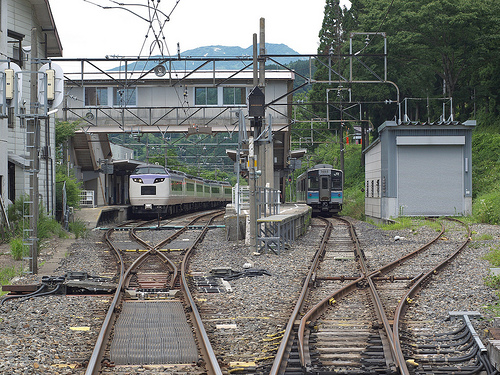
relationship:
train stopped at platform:
[129, 161, 235, 218] [75, 204, 138, 226]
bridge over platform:
[61, 105, 250, 135] [75, 204, 138, 226]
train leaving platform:
[129, 161, 235, 218] [75, 204, 138, 226]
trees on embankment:
[305, 0, 499, 121] [299, 108, 499, 220]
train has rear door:
[293, 166, 345, 217] [320, 176, 331, 199]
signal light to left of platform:
[155, 65, 165, 77] [257, 200, 319, 253]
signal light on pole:
[36, 61, 67, 111] [29, 26, 43, 275]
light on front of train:
[154, 176, 165, 184] [129, 161, 235, 218]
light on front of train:
[131, 176, 142, 184] [129, 161, 235, 218]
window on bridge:
[84, 87, 109, 106] [61, 69, 294, 135]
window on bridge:
[113, 87, 136, 106] [61, 69, 294, 135]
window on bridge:
[196, 84, 219, 104] [61, 69, 294, 135]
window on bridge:
[223, 85, 246, 105] [61, 69, 294, 135]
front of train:
[128, 165, 170, 216] [129, 161, 235, 218]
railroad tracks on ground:
[88, 209, 225, 374] [0, 205, 500, 374]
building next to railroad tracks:
[0, 3, 64, 226] [88, 209, 225, 374]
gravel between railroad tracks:
[185, 214, 324, 373] [88, 209, 225, 374]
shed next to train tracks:
[361, 118, 476, 219] [270, 218, 472, 374]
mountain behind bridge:
[113, 41, 312, 70] [61, 69, 294, 135]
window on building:
[13, 48, 25, 65] [0, 3, 64, 226]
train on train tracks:
[293, 166, 345, 217] [270, 218, 472, 374]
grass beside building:
[39, 216, 71, 241] [0, 3, 64, 226]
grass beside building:
[11, 237, 25, 260] [0, 3, 64, 226]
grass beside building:
[0, 263, 28, 286] [0, 3, 64, 226]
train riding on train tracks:
[293, 166, 345, 217] [270, 218, 472, 374]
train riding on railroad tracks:
[129, 161, 235, 218] [88, 209, 225, 374]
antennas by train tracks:
[405, 66, 458, 125] [270, 218, 472, 374]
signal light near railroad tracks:
[36, 61, 67, 111] [88, 209, 225, 374]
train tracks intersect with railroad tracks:
[270, 218, 472, 374] [88, 209, 225, 374]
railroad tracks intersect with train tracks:
[88, 209, 225, 374] [270, 218, 472, 374]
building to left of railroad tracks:
[0, 3, 64, 226] [88, 209, 225, 374]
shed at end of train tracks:
[361, 118, 476, 219] [270, 218, 472, 374]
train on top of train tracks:
[293, 166, 345, 217] [270, 218, 472, 374]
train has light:
[129, 161, 235, 218] [131, 176, 142, 184]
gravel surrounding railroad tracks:
[185, 214, 324, 373] [88, 209, 225, 374]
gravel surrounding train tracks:
[185, 214, 324, 373] [270, 218, 472, 374]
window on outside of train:
[171, 179, 183, 191] [129, 161, 235, 218]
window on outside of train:
[185, 180, 196, 191] [129, 161, 235, 218]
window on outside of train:
[195, 180, 203, 192] [129, 161, 235, 218]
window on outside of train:
[204, 185, 212, 193] [129, 161, 235, 218]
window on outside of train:
[211, 186, 219, 195] [129, 161, 235, 218]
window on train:
[333, 178, 341, 189] [293, 166, 345, 217]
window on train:
[307, 177, 318, 190] [293, 166, 345, 217]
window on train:
[302, 179, 307, 192] [293, 166, 345, 217]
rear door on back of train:
[320, 176, 331, 199] [293, 166, 345, 217]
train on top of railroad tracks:
[129, 161, 235, 218] [88, 209, 225, 374]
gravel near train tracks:
[185, 214, 324, 373] [270, 218, 472, 374]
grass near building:
[39, 216, 71, 241] [0, 3, 64, 226]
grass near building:
[11, 237, 25, 260] [0, 3, 64, 226]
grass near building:
[0, 263, 28, 286] [0, 3, 64, 226]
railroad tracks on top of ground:
[88, 209, 225, 374] [0, 205, 500, 374]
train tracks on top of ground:
[270, 218, 472, 374] [0, 205, 500, 374]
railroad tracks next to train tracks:
[88, 209, 225, 374] [270, 218, 472, 374]